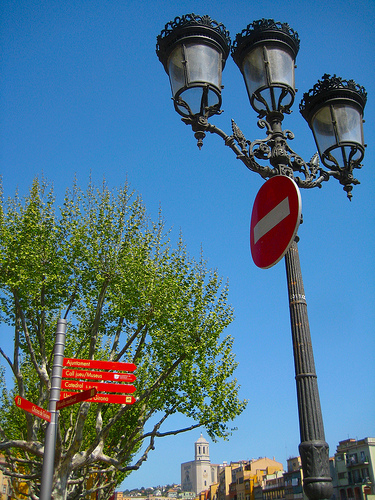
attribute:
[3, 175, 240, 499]
tree — green, branching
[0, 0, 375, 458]
sky — blue, clear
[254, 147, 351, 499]
post — black, gray, metal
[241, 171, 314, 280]
sign — red, white